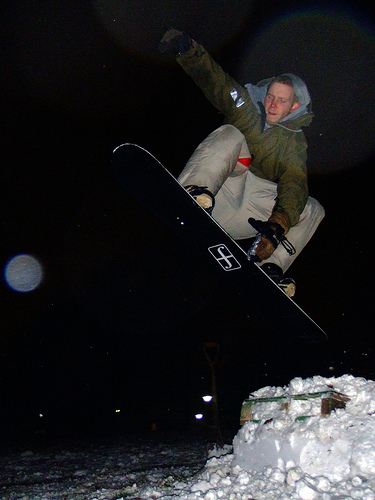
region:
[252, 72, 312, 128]
boy has grey hood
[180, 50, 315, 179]
boy has green jacket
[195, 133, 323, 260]
boy has grey pants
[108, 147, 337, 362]
black and white board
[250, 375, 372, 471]
white snow under boy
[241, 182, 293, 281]
black and brown gloves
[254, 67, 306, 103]
boy has short hair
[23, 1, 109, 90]
black sky behind boy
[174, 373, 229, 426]
white lights under boy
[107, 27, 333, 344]
guy doing a trick on a snowboard.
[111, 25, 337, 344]
guy doing a trick on a snowboard.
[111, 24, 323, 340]
guy doing a trick on a snowboard.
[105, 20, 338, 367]
A snowboarder in mid air after a jump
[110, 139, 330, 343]
A black snow board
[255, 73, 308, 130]
A man in hood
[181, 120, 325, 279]
Mens baige snow pants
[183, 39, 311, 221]
A mens green snow jacket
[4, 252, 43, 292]
An out of focus moon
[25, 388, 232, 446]
Lights of in distance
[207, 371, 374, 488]
Snow piled into ramp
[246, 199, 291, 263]
Brown mens snow glove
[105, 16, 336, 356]
A man doing a trick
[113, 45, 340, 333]
A man on snow board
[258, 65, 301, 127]
head of a person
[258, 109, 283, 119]
mouth of a person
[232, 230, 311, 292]
leg of a person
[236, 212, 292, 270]
hand of a person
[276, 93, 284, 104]
eye of a person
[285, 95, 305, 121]
ear of a person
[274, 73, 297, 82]
hair of a person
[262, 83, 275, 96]
eye brow of a person